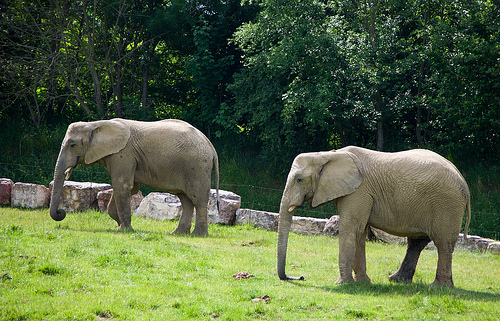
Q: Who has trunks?
A: Elephants.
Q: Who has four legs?
A: One elephant.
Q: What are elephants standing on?
A: Green grass.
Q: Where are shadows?
A: On the grass.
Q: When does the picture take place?
A: During daytime.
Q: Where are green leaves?
A: On trees.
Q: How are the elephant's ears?
A: Big.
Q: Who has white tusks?
A: The elephants.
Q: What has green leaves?
A: The trees.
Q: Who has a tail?
A: Both elephants.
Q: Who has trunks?
A: The elephants.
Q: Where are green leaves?
A: On the trees.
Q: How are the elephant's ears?
A: Big.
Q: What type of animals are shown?
A: Elephants.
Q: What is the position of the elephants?
A: Standing.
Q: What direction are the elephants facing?
A: Left.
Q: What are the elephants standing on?
A: Grass.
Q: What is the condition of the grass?
A: Yellowish green.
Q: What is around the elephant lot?
A: Large rocks.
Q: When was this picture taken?
A: Daytime.